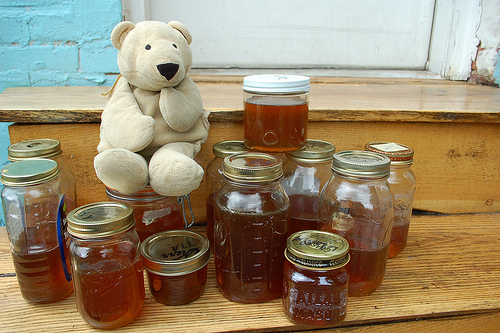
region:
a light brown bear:
[94, 16, 211, 199]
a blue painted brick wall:
[0, 1, 129, 225]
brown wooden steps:
[0, 81, 495, 329]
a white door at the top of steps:
[137, 1, 449, 71]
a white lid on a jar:
[240, 71, 313, 153]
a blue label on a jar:
[52, 193, 80, 284]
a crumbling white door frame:
[452, 6, 499, 86]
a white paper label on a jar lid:
[369, 139, 409, 157]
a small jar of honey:
[138, 232, 219, 308]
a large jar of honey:
[210, 149, 290, 305]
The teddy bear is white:
[95, 18, 217, 188]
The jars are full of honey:
[12, 121, 408, 317]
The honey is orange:
[247, 103, 303, 143]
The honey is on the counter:
[35, 117, 453, 329]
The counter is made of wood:
[382, 118, 482, 324]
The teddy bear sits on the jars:
[27, 21, 212, 329]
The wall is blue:
[18, 3, 101, 88]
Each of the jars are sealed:
[30, 97, 418, 278]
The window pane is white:
[156, 6, 480, 50]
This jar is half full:
[317, 173, 394, 268]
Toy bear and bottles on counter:
[12, 25, 480, 329]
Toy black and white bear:
[91, 17, 216, 197]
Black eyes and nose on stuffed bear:
[142, 37, 190, 77]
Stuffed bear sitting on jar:
[82, 3, 209, 225]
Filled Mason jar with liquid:
[275, 225, 352, 325]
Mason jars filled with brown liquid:
[0, 66, 457, 328]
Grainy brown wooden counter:
[5, 205, 498, 330]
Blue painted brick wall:
[4, 5, 135, 87]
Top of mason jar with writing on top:
[142, 222, 212, 277]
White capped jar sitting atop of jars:
[205, 60, 334, 188]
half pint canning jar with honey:
[140, 225, 213, 313]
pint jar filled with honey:
[274, 225, 356, 325]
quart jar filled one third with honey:
[321, 151, 393, 297]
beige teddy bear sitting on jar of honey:
[82, 16, 213, 198]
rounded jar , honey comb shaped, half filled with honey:
[2, 153, 78, 315]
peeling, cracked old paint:
[447, 12, 498, 87]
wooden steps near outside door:
[410, 71, 495, 329]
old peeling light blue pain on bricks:
[6, 5, 113, 82]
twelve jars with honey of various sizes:
[15, 73, 458, 321]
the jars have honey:
[214, 72, 426, 326]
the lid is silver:
[228, 147, 280, 187]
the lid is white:
[236, 63, 303, 91]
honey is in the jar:
[210, 200, 286, 310]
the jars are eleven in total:
[2, 86, 438, 321]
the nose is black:
[155, 60, 193, 85]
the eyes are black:
[128, 32, 188, 61]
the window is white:
[146, 10, 453, 62]